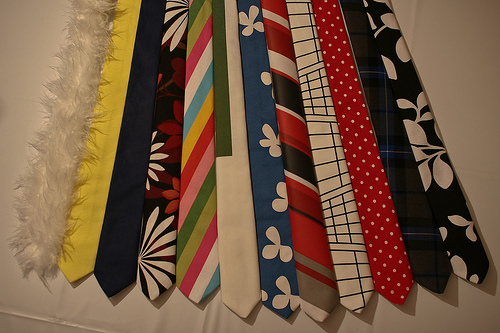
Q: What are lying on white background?
A: Neckties.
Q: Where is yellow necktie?
A: Next to white fuzzy necktie.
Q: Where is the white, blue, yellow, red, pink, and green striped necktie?
A: Next to white and green necktie.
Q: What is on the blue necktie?
A: White flowers.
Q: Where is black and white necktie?
A: Next to the red with white dots necktie.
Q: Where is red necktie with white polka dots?
A: Next to the white and black necktie.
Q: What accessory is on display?
A: Tie.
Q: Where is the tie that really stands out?
A: At left.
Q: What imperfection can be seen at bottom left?
A: Crease.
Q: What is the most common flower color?
A: White.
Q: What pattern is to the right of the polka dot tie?
A: Plaid.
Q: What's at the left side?
A: Fuzzy white tie.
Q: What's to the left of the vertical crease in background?
A: Diagonally striped tie.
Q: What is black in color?
A: The tie.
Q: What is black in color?
A: The tie.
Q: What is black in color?
A: The tie.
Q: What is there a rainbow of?
A: Neck ties.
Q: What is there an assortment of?
A: Patterned neckties.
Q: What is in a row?
A: An array of ties.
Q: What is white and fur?
A: A necktie.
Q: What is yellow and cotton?
A: A neck tie.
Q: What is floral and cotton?
A: A neck tie.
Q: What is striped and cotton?
A: A necktie.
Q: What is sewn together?
A: Ties.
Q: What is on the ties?
A: Patterns.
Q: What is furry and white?
A: A tie.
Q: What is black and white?
A: A tie.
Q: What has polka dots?
A: A tie.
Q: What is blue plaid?
A: A tie.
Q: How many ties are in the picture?
A: 12.